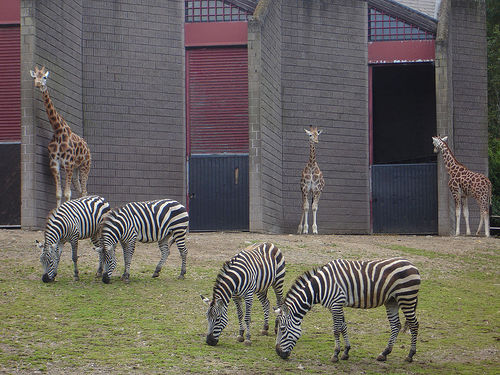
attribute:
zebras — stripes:
[18, 173, 471, 369]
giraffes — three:
[29, 70, 481, 217]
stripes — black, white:
[324, 263, 400, 293]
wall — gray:
[0, 0, 493, 241]